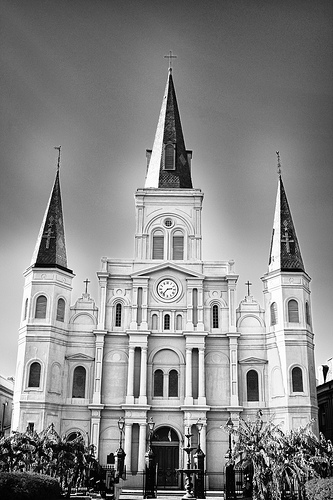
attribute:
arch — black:
[163, 311, 171, 329]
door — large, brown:
[146, 421, 182, 491]